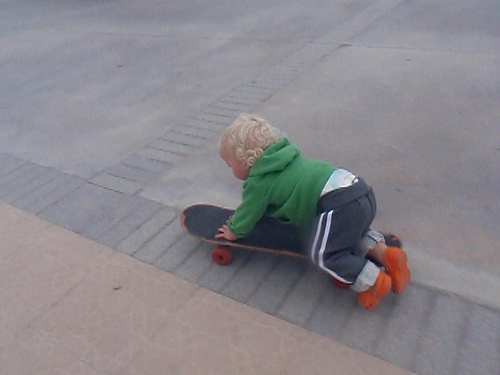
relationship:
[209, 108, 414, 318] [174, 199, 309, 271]
boy on skate board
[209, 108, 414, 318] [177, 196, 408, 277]
boy on skateboard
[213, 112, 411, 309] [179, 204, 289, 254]
boy on a skateboard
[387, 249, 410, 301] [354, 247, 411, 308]
shoe on toddlers feet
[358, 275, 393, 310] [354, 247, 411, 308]
shoe on toddlers feet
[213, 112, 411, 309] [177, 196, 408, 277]
boy on skateboard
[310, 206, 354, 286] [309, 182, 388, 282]
stripes on pants